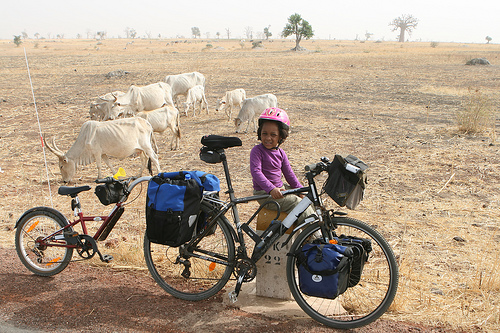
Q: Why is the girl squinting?
A: It's bright.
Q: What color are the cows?
A: White.